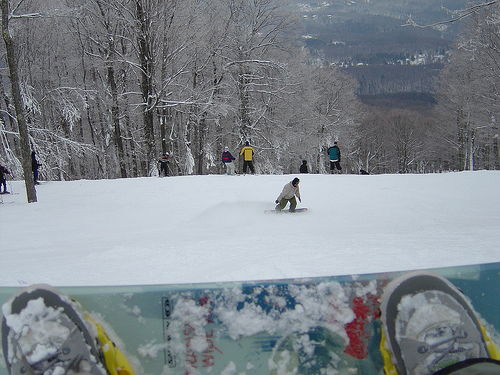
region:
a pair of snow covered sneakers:
[1, 274, 497, 372]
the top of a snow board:
[1, 264, 498, 372]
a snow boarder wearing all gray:
[272, 175, 304, 213]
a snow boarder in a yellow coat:
[237, 141, 259, 175]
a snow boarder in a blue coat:
[324, 134, 344, 171]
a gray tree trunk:
[2, 5, 36, 202]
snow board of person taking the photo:
[7, 262, 495, 372]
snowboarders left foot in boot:
[10, 278, 97, 373]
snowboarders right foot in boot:
[381, 268, 488, 373]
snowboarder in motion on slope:
[269, 175, 306, 220]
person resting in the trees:
[32, 146, 42, 189]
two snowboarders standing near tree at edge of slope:
[220, 143, 264, 182]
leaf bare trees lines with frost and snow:
[0, 0, 357, 177]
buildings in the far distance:
[307, 46, 467, 72]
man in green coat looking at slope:
[325, 135, 340, 173]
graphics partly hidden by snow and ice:
[155, 279, 375, 374]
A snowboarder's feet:
[1, 275, 491, 374]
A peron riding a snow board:
[275, 175, 311, 217]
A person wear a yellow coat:
[238, 140, 256, 174]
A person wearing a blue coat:
[324, 139, 343, 172]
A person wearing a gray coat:
[274, 175, 302, 209]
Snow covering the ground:
[1, 172, 498, 284]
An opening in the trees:
[297, 0, 470, 106]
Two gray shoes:
[4, 277, 487, 374]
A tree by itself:
[0, 1, 37, 202]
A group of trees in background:
[0, 2, 351, 172]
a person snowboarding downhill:
[256, 170, 318, 227]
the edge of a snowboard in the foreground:
[6, 287, 483, 369]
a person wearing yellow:
[239, 135, 263, 181]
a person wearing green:
[320, 138, 345, 183]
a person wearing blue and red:
[214, 139, 242, 182]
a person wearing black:
[293, 147, 311, 175]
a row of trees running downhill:
[2, 8, 498, 180]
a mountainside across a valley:
[248, 2, 477, 122]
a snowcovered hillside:
[37, 169, 490, 275]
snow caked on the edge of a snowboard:
[121, 273, 398, 374]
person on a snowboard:
[267, 177, 306, 212]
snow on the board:
[170, 280, 353, 349]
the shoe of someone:
[388, 276, 492, 374]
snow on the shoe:
[8, 296, 71, 363]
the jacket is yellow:
[240, 144, 254, 159]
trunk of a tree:
[2, 0, 37, 202]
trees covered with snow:
[2, 1, 498, 181]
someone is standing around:
[31, 152, 41, 187]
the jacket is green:
[328, 144, 338, 161]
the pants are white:
[224, 162, 234, 173]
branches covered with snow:
[29, 68, 122, 168]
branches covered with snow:
[29, 82, 100, 163]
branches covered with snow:
[23, 62, 102, 164]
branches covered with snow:
[20, 71, 115, 177]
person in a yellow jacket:
[236, 140, 256, 174]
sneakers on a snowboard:
[2, 261, 498, 373]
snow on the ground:
[0, 171, 498, 286]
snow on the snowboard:
[0, 263, 498, 373]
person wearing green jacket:
[326, 140, 343, 173]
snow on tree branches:
[3, 2, 293, 177]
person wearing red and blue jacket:
[221, 144, 238, 174]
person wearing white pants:
[221, 145, 236, 176]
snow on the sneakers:
[6, 275, 492, 374]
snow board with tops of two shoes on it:
[1, 256, 498, 371]